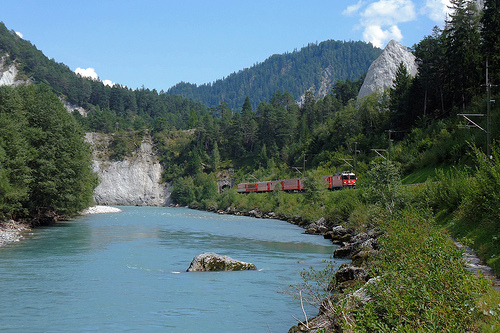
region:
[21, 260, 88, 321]
the water is calm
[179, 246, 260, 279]
rock in the water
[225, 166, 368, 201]
train on the tracks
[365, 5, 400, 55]
clouds over the mountain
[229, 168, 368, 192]
a red train on the tracks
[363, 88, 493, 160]
poles next to the tracks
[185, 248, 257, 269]
a rock in the water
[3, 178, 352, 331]
water next to the train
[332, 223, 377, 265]
rocks next to the water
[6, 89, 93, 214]
a large tree next to the water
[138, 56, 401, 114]
a mountain behind the train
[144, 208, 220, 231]
small waves in the water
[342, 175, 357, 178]
the windshield on the train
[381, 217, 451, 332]
bushes next to the water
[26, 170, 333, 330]
lake in the valley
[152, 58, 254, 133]
tree filled mountain range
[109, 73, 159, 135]
trees on the mountain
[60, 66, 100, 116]
trees on the mountain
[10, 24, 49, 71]
trees on the mountain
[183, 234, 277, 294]
large rock in middle of water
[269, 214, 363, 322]
rocks along the shore line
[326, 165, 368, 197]
the front of a red train passing by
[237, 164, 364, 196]
the large red train by the water side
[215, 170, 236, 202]
the tunnel the red train came from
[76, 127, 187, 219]
a large white rock wall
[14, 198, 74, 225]
downed trees by the edge of water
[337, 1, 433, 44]
clouds in the blue sky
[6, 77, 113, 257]
Section of a forest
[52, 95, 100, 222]
Section of a forest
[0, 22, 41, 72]
Section of a forest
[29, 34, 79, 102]
Section of a forest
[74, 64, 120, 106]
Section of a forest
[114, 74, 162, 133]
Section of a forest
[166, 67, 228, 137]
Section of a forest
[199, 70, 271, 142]
Section of a forest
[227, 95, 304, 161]
Section of a forest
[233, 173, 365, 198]
red and gray train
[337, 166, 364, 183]
black front of train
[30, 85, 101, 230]
green evergreen tree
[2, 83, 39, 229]
green evergreen tree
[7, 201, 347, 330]
clear blue river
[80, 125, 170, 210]
rock face behind river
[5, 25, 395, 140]
mountain in background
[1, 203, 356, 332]
large wide blue river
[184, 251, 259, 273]
large rock in water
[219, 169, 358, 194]
large long red train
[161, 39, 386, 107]
large green forested mountain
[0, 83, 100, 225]
large round green trees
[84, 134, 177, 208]
grey white cliff face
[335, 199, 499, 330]
large long row of bushes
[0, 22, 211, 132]
large green tree covered hill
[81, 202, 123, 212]
white round hill ground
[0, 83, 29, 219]
large tall leafy green tree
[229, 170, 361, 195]
large long red train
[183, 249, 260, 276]
large jagged rock in water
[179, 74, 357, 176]
large green forested hill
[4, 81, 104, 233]
large patch of green trees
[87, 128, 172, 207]
large wide grey cliff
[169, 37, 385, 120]
large tall green forested mountain